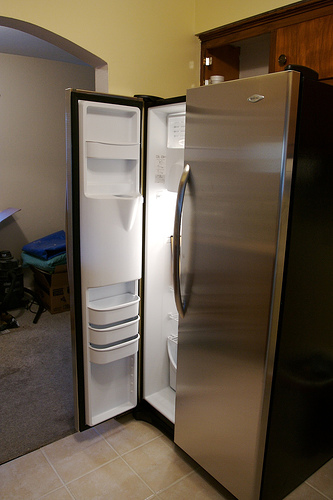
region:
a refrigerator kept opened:
[64, 85, 244, 489]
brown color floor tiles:
[53, 437, 178, 494]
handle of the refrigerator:
[164, 164, 183, 312]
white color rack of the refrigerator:
[91, 137, 146, 386]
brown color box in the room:
[30, 264, 74, 317]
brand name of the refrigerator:
[243, 92, 268, 102]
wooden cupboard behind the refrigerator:
[204, 19, 331, 76]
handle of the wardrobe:
[278, 54, 288, 65]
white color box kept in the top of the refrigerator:
[206, 72, 225, 83]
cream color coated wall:
[98, 12, 172, 60]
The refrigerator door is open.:
[66, 74, 177, 329]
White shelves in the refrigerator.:
[80, 298, 149, 363]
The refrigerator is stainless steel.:
[134, 91, 295, 326]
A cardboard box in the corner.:
[26, 259, 73, 313]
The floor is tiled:
[47, 437, 152, 493]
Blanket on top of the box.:
[25, 227, 64, 271]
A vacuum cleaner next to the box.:
[0, 251, 46, 326]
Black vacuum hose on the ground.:
[24, 285, 44, 322]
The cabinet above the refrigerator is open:
[204, 37, 270, 74]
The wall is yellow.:
[89, 16, 203, 78]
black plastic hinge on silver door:
[284, 62, 320, 78]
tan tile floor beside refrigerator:
[136, 416, 177, 465]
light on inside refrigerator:
[152, 196, 176, 234]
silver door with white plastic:
[71, 88, 145, 430]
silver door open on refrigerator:
[65, 87, 145, 431]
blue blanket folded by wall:
[24, 229, 65, 255]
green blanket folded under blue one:
[18, 253, 65, 265]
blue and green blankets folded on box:
[24, 224, 73, 314]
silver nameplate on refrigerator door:
[244, 94, 264, 102]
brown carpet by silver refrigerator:
[7, 395, 82, 429]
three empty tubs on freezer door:
[86, 290, 142, 363]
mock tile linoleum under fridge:
[3, 402, 330, 498]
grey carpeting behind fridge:
[0, 288, 82, 465]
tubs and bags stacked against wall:
[22, 219, 75, 325]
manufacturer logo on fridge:
[244, 90, 265, 102]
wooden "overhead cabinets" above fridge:
[191, 0, 331, 85]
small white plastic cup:
[207, 71, 226, 86]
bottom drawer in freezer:
[165, 329, 180, 393]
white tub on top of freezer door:
[85, 134, 140, 163]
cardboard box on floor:
[29, 263, 72, 316]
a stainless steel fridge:
[60, 64, 280, 498]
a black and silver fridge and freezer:
[58, 64, 332, 496]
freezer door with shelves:
[74, 91, 151, 428]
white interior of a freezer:
[81, 101, 152, 416]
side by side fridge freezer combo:
[63, 74, 294, 496]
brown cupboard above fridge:
[190, 5, 328, 94]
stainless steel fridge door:
[165, 69, 292, 484]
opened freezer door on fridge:
[47, 78, 293, 489]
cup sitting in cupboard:
[205, 61, 231, 89]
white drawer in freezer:
[166, 330, 186, 408]